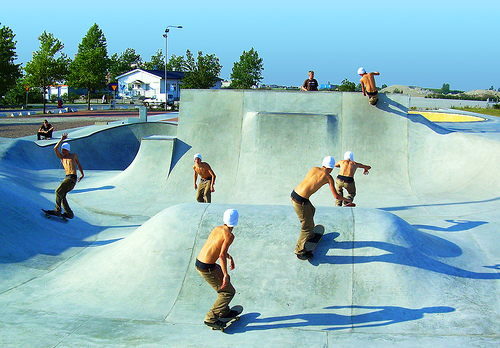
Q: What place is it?
A: It is a park.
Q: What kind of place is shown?
A: It is a park.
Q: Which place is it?
A: It is a park.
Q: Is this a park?
A: Yes, it is a park.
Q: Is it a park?
A: Yes, it is a park.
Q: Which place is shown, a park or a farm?
A: It is a park.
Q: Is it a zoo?
A: No, it is a park.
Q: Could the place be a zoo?
A: No, it is a park.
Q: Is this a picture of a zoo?
A: No, the picture is showing a park.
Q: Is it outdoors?
A: Yes, it is outdoors.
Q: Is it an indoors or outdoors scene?
A: It is outdoors.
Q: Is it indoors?
A: No, it is outdoors.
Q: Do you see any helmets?
A: No, there are no helmets.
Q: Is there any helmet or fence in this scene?
A: No, there are no helmets or fences.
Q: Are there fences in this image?
A: No, there are no fences.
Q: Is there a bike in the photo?
A: No, there are no bikes.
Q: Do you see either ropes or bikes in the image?
A: No, there are no bikes or ropes.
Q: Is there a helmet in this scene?
A: No, there are no helmets.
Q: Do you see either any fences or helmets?
A: No, there are no helmets or fences.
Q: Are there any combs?
A: No, there are no combs.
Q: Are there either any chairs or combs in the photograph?
A: No, there are no combs or chairs.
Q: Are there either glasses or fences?
A: No, there are no glasses or fences.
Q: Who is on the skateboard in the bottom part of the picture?
A: The men are on the skateboard.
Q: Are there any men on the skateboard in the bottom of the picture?
A: Yes, there are men on the skateboard.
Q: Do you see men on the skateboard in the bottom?
A: Yes, there are men on the skateboard.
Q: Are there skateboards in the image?
A: Yes, there is a skateboard.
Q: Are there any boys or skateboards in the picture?
A: Yes, there is a skateboard.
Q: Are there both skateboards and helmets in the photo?
A: No, there is a skateboard but no helmets.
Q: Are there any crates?
A: No, there are no crates.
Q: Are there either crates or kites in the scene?
A: No, there are no crates or kites.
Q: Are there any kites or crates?
A: No, there are no crates or kites.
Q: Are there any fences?
A: No, there are no fences.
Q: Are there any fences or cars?
A: No, there are no fences or cars.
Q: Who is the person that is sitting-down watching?
A: The person is watching the man.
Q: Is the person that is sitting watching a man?
A: Yes, the person is watching a man.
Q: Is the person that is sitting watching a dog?
A: No, the person is watching a man.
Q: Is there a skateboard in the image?
A: Yes, there is a skateboard.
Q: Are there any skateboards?
A: Yes, there is a skateboard.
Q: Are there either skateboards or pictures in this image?
A: Yes, there is a skateboard.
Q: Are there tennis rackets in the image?
A: No, there are no tennis rackets.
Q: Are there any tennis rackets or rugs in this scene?
A: No, there are no tennis rackets or rugs.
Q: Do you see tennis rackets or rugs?
A: No, there are no tennis rackets or rugs.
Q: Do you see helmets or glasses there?
A: No, there are no glasses or helmets.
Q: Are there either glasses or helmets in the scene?
A: No, there are no glasses or helmets.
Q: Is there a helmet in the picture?
A: No, there are no helmets.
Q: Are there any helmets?
A: No, there are no helmets.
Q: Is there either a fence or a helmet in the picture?
A: No, there are no helmets or fences.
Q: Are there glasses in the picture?
A: No, there are no glasses.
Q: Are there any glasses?
A: No, there are no glasses.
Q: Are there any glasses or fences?
A: No, there are no glasses or fences.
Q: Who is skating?
A: The men are skating.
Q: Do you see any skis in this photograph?
A: No, there are no skis.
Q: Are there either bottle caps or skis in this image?
A: No, there are no skis or bottle caps.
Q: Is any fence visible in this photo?
A: No, there are no fences.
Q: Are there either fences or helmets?
A: No, there are no fences or helmets.